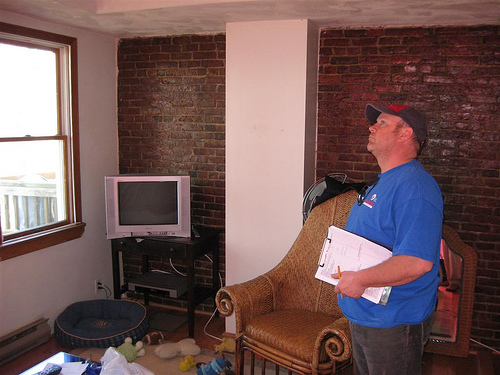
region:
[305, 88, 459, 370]
Man holding a clipboard.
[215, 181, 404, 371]
Brown chair in a room.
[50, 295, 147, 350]
Dog bed in a room.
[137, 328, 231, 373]
Toys on the floor.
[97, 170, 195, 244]
Television in a corner.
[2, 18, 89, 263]
Window with no curtains.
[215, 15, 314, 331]
White column against a brick wall.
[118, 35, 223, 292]
A brick wall behind a television.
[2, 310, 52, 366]
Radiator along the base of a wall.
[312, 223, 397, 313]
Clipboard full of papers.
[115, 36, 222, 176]
Red brick wall in corner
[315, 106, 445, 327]
Man looking at the ceiling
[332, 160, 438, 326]
Blue shirt worn by the man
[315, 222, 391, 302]
Clipboard held by the man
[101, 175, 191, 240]
Computer or TV in corner of room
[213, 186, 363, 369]
Rust colored chair next to the man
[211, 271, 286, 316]
Right arm of rust colored chair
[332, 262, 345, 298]
Pencil in man's left hand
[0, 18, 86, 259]
Dark brown window frame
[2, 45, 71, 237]
Glass window pane in window frame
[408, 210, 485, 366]
a mirror propped up against the wall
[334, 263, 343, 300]
a pencil in the man's hand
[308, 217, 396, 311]
a clipboard in the man's hand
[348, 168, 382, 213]
a pair of sunglasses tucked in the man's shirt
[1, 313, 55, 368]
a heater on the wall under the window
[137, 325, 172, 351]
a small football on the floor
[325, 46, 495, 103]
a wall made of bricks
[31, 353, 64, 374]
part of a remote control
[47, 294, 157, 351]
a pet's bed in the floor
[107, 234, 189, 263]
a drawer in the t.v. stand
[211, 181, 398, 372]
A brown chair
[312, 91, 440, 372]
Man holding a clipboard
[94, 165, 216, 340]
TV on a stand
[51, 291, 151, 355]
Blue with brown trim pet bed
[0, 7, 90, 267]
Window with no curtains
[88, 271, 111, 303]
Electrical outlet with 2 plugs in it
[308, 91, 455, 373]
A man wearing a blue shirt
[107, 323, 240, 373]
Assorted toys on the floor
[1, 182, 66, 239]
Building outside of window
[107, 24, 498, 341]
A brick wall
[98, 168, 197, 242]
The TV is pre-flatscreen technology.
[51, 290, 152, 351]
This dog bed has no dog in it.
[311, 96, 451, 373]
This man is holding a clipboard and pencil.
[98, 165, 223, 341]
The table is holding a TV and a VCR unit.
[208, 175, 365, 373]
The chair is a tight-weaved rattan.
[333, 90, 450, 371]
The man is wearing a blue T-shirt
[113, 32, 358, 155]
The walls of this room are brick.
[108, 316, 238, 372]
There are toys all over the floor.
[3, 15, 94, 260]
The window has a view of a balcony.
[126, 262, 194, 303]
The VCR is turned on.